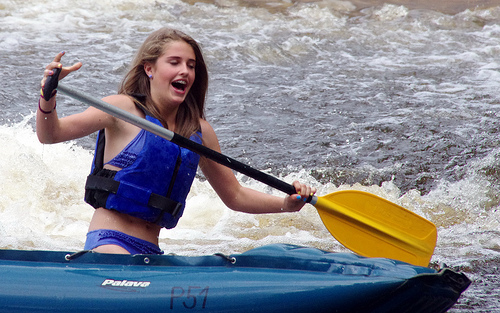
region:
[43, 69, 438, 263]
a yellow paddle with a metal stick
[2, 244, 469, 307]
a blue kayak on the water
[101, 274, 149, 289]
white letters on a blue kayak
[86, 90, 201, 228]
woman wearing a security vest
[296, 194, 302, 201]
blue nail polish on a thumb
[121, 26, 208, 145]
woman with long light brown hair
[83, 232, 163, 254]
a blue bikini bottom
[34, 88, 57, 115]
woman wearing red bracelets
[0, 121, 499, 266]
white foam on the water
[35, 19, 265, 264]
this is a lady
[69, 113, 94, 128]
the lady is light skinned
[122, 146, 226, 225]
this is a life saving jacket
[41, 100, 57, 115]
this is a wrist band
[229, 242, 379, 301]
this is a boat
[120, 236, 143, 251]
the pant is blue in color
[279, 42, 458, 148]
this is a water body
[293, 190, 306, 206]
the nail is painted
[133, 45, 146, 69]
this is the hair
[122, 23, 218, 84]
Girl has brown hair.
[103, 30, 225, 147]
Girl has long hair.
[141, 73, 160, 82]
Small earring on girl's ear.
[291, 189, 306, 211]
Blue nail polish on girl's finger.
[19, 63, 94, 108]
Girl holding paddle in hands.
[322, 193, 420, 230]
End of paddle is yellow.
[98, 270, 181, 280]
White writing on side of kayak.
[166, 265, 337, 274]
Kayak is blue in color.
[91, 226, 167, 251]
Girl wearing blue bikini bottoms.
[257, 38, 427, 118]
Water is bumpy.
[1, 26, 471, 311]
girl in a one person watercraft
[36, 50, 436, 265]
girl is holding a paddle with both hands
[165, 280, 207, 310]
number and letter identification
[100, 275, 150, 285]
brand of watercraft in white text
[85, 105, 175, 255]
girl is wearing a blue two-piece bathing suit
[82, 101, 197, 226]
girl is wearing a blue life vest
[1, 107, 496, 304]
white water behind watercraft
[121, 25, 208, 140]
girl's light brown hair is loose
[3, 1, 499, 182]
water appears to be running quickly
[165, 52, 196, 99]
girl's eyes are closed and her mouth is open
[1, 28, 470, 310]
woman in a boat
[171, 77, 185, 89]
the mouth is open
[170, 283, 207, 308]
the writing says p51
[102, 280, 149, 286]
white writing on boat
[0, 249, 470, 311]
the boat is blue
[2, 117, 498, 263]
the wave is white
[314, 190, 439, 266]
the paddle is yellow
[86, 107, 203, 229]
the vest is purple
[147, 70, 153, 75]
girl has an earring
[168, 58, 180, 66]
eye of a girl